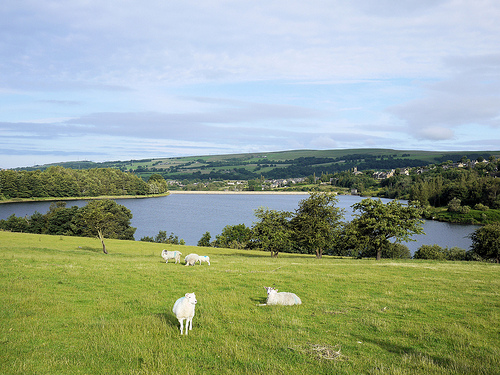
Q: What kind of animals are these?
A: Sheep.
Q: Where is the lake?
A: Behind the field and trees.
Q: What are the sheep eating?
A: Grass.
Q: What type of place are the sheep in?
A: A field.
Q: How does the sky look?
A: Blue with some clouds.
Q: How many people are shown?
A: None.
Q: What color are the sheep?
A: White.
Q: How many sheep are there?
A: At least 4.